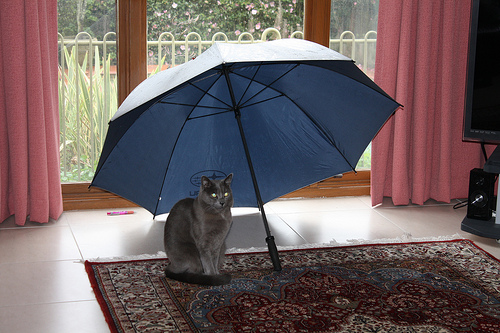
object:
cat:
[160, 172, 235, 286]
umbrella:
[86, 38, 406, 272]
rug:
[81, 237, 499, 332]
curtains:
[1, 0, 63, 224]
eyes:
[208, 191, 231, 197]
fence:
[56, 28, 378, 78]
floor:
[0, 205, 499, 332]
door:
[119, 0, 329, 108]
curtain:
[366, 0, 500, 207]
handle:
[264, 235, 285, 272]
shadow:
[118, 212, 288, 253]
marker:
[103, 210, 137, 217]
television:
[456, 0, 498, 144]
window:
[56, 0, 113, 185]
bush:
[59, 1, 315, 65]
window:
[142, 0, 304, 72]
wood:
[114, 0, 146, 102]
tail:
[163, 268, 231, 288]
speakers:
[464, 165, 496, 219]